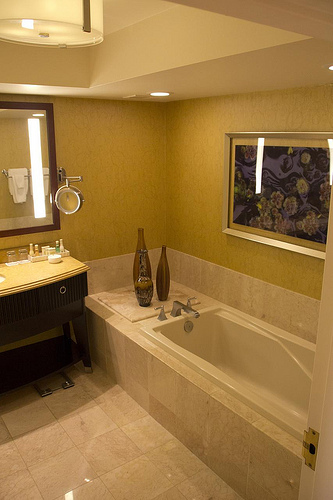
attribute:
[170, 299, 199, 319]
faucet — silver, bathtub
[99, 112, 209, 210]
wall — yellow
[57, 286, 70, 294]
handle — silver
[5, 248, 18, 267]
glass — clear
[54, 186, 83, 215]
mirror — bathroom, round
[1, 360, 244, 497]
floor — bathroom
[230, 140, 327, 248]
artwork — framed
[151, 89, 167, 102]
light — round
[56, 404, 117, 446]
tile — beige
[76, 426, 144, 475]
tile — beige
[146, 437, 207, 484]
tile — beige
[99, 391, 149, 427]
tile — beige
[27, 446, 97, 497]
tile — beige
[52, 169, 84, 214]
mirror — bathroom, mounted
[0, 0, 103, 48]
light — round, hanging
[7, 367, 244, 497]
tiles — square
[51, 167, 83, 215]
mirror — round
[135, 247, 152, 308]
brown vase — tall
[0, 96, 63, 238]
mirror — Wood framed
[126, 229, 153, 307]
vase — tall, brown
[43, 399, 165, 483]
floor — shiny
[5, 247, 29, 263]
glasses — clear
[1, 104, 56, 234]
mirror — framed, brown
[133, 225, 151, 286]
vase — decoration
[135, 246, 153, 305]
vase — decoration, decorative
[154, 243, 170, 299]
vase — decoration, tall, brown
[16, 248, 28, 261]
glass — clear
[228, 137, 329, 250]
border — yellow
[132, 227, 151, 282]
vase — decorative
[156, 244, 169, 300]
vase — decorative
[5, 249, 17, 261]
glass — upside down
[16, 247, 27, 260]
glass — upside down